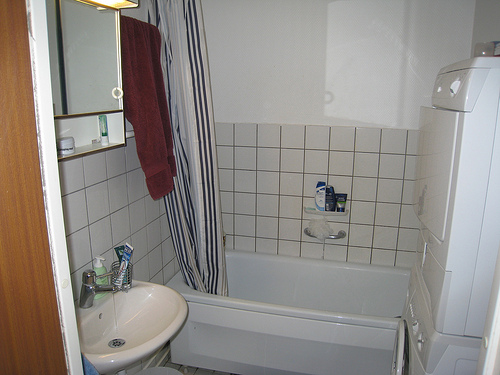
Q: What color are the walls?
A: White.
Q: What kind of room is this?
A: Bathroom.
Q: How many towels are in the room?
A: One.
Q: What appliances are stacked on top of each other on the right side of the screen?
A: Washer and dryer.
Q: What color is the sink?
A: White.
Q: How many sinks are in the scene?
A: One.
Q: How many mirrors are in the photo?
A: One.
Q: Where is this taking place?
A: In a bathroom.